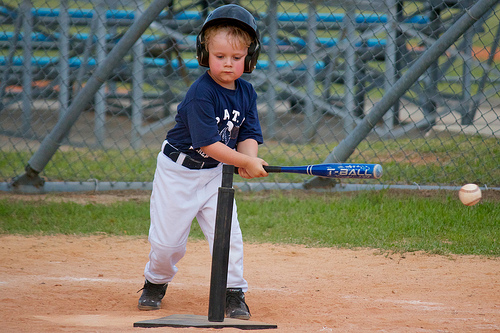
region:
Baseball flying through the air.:
[452, 178, 487, 213]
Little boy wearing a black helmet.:
[188, 2, 265, 88]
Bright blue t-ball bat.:
[259, 149, 399, 199]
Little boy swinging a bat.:
[123, 16, 385, 190]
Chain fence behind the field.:
[305, 17, 462, 149]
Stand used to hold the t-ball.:
[153, 148, 255, 330]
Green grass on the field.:
[344, 199, 456, 246]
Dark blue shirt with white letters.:
[165, 69, 272, 164]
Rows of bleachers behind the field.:
[275, 7, 406, 106]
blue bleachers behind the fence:
[21, 5, 435, 87]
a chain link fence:
[1, 6, 498, 183]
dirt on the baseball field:
[27, 221, 478, 328]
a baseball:
[455, 176, 480, 202]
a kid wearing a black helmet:
[145, 5, 280, 310]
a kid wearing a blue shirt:
[140, 5, 290, 322]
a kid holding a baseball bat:
[140, 2, 380, 288]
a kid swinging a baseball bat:
[160, 10, 375, 305]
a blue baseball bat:
[257, 161, 378, 172]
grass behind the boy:
[258, 192, 480, 252]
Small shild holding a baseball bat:
[139, 4, 285, 314]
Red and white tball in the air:
[441, 157, 477, 217]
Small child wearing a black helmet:
[135, 3, 292, 308]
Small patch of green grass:
[8, 194, 58, 234]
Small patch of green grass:
[70, 189, 117, 224]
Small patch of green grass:
[260, 204, 298, 233]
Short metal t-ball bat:
[262, 150, 389, 196]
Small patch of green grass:
[327, 201, 374, 239]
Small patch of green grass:
[389, 187, 449, 241]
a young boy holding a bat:
[138, 5, 383, 318]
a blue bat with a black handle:
[234, 163, 382, 180]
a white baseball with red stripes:
[457, 182, 482, 205]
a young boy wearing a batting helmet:
[137, 5, 267, 320]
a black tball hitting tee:
[133, 162, 278, 330]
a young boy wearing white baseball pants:
[136, 3, 267, 319]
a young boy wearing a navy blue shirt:
[137, 6, 267, 318]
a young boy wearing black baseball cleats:
[135, 4, 265, 319]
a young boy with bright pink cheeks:
[140, 4, 270, 317]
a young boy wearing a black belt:
[138, 4, 265, 319]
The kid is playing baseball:
[47, 14, 484, 328]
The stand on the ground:
[198, 155, 244, 326]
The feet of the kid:
[138, 279, 262, 323]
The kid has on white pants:
[139, 146, 248, 292]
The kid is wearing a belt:
[162, 140, 219, 172]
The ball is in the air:
[451, 178, 483, 212]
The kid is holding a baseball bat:
[231, 149, 388, 184]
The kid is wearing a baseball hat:
[191, 3, 266, 83]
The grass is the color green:
[306, 196, 466, 246]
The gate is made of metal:
[10, 13, 161, 181]